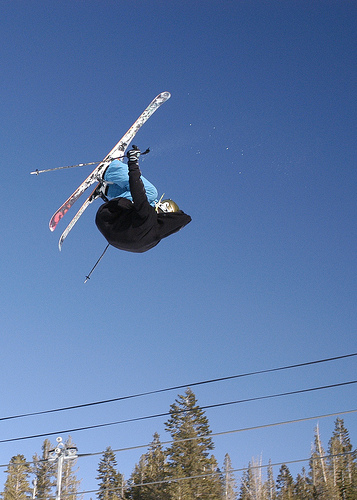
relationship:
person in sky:
[89, 140, 195, 256] [2, 2, 356, 499]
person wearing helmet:
[89, 140, 195, 256] [156, 194, 183, 227]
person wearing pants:
[89, 140, 195, 256] [101, 155, 160, 207]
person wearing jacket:
[89, 140, 195, 256] [94, 158, 193, 255]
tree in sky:
[139, 386, 220, 500] [2, 2, 356, 499]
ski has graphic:
[45, 88, 174, 237] [49, 190, 75, 230]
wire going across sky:
[1, 352, 356, 425] [2, 2, 356, 499]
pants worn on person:
[101, 155, 160, 207] [89, 140, 195, 256]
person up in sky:
[89, 140, 195, 256] [2, 2, 356, 499]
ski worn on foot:
[45, 88, 174, 237] [97, 153, 122, 187]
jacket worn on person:
[94, 158, 193, 255] [89, 140, 195, 256]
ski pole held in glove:
[28, 145, 153, 179] [123, 142, 144, 170]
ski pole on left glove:
[28, 145, 153, 179] [123, 142, 144, 170]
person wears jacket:
[89, 140, 195, 256] [94, 158, 193, 255]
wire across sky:
[1, 352, 356, 425] [2, 2, 356, 499]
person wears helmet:
[89, 140, 195, 256] [156, 194, 183, 227]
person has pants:
[89, 140, 195, 256] [101, 155, 160, 207]